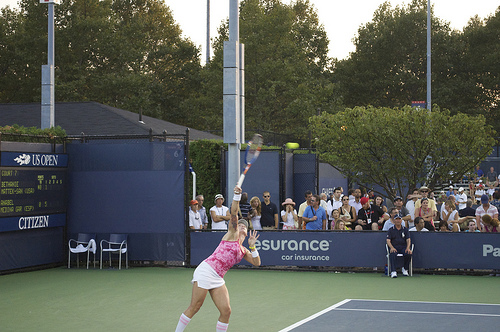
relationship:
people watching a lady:
[189, 188, 499, 232] [175, 184, 264, 331]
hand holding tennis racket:
[232, 183, 242, 196] [235, 132, 265, 189]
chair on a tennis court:
[66, 230, 98, 270] [1, 262, 498, 329]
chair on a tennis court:
[99, 230, 129, 275] [1, 262, 498, 329]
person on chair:
[386, 219, 415, 279] [381, 233, 420, 280]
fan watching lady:
[298, 195, 328, 234] [175, 184, 264, 331]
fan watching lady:
[277, 195, 301, 234] [175, 184, 264, 331]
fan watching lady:
[206, 188, 228, 229] [175, 184, 264, 331]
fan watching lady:
[181, 198, 203, 234] [175, 184, 264, 331]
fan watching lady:
[471, 195, 494, 225] [175, 184, 264, 331]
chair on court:
[66, 230, 98, 270] [262, 274, 498, 328]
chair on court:
[99, 230, 129, 275] [262, 274, 498, 328]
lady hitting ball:
[176, 158, 264, 329] [282, 140, 297, 150]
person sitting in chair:
[386, 219, 415, 279] [381, 233, 420, 280]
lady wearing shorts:
[175, 184, 264, 331] [190, 255, 228, 291]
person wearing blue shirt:
[304, 198, 327, 236] [299, 207, 329, 234]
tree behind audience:
[309, 106, 488, 185] [268, 180, 483, 223]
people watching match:
[278, 183, 475, 239] [12, 131, 470, 324]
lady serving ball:
[175, 184, 264, 331] [284, 139, 298, 149]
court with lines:
[276, 287, 497, 327] [333, 280, 383, 319]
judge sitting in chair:
[385, 216, 415, 265] [379, 243, 422, 275]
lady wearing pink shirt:
[175, 184, 264, 331] [207, 237, 242, 278]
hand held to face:
[285, 203, 289, 210] [284, 200, 293, 210]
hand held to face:
[288, 204, 294, 210] [284, 200, 293, 210]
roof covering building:
[2, 100, 225, 142] [2, 101, 226, 142]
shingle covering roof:
[124, 122, 134, 130] [2, 100, 225, 142]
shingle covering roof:
[88, 121, 99, 125] [2, 100, 225, 142]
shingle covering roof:
[101, 108, 111, 113] [2, 100, 225, 142]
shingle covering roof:
[57, 119, 67, 124] [2, 100, 225, 142]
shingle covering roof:
[21, 108, 31, 113] [2, 100, 225, 142]